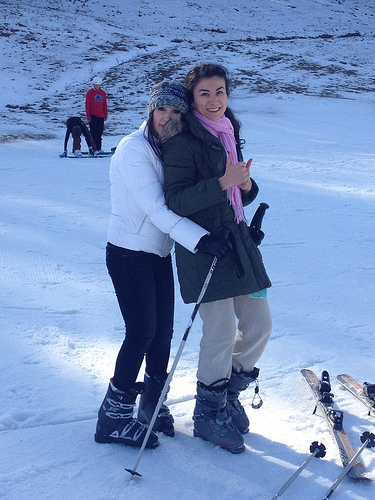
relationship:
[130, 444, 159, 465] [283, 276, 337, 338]
skis are on snow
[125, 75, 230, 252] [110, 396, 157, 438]
women are wearing boots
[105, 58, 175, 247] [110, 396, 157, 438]
woman wearing boots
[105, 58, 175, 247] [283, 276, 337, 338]
woman standing on snow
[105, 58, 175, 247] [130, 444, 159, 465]
woman holding skis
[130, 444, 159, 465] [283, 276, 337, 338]
skis are in snow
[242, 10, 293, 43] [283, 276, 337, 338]
ground can be seen through snow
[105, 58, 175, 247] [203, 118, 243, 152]
woman wearing scarf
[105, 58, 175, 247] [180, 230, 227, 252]
woman wearing gloves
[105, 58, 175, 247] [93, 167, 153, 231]
woman wearing jacket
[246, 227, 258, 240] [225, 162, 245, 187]
glove on hand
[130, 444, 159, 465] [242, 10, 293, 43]
skis are on ground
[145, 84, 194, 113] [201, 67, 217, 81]
hat on head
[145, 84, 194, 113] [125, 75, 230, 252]
hat on women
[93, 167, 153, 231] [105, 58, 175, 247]
jacket on woman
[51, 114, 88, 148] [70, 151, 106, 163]
boy checking h snowboard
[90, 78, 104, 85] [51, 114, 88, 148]
helmet on boy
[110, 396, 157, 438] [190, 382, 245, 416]
boots are on feet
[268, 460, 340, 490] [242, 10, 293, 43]
poles are on ground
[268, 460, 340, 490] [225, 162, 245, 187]
poles are in hand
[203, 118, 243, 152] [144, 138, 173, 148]
scarf on neck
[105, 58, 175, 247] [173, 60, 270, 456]
woman has head in window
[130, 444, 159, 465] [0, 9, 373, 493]
skis are on ground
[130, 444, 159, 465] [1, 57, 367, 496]
skis are on ground